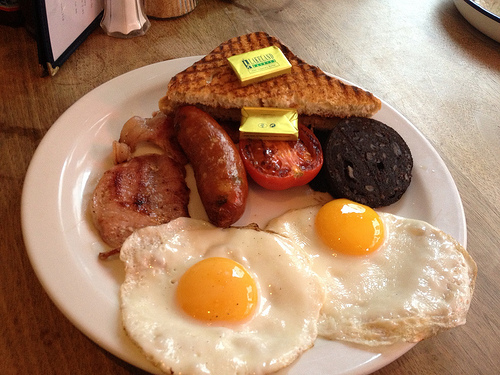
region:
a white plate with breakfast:
[21, 32, 476, 373]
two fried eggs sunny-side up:
[115, 199, 472, 374]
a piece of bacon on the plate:
[92, 116, 189, 245]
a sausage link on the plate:
[175, 112, 245, 225]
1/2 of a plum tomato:
[237, 126, 324, 193]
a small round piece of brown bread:
[322, 117, 414, 207]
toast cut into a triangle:
[155, 30, 380, 120]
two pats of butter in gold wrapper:
[223, 44, 298, 135]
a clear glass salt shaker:
[100, 3, 151, 35]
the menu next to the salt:
[29, 1, 101, 78]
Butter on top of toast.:
[230, 46, 290, 75]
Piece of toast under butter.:
[196, 55, 297, 95]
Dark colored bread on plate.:
[345, 132, 407, 169]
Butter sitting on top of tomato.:
[236, 108, 317, 147]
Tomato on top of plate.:
[248, 137, 314, 209]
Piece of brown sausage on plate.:
[196, 108, 246, 206]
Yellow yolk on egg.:
[326, 203, 378, 240]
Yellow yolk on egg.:
[202, 259, 255, 313]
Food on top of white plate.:
[77, 80, 373, 305]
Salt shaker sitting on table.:
[100, 4, 165, 40]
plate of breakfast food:
[16, 25, 476, 373]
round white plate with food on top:
[20, 45, 474, 374]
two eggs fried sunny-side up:
[118, 200, 477, 373]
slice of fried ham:
[86, 113, 189, 263]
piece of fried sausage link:
[171, 106, 248, 226]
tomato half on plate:
[241, 129, 325, 194]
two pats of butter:
[228, 43, 307, 141]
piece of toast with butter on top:
[164, 27, 384, 117]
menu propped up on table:
[21, 0, 98, 80]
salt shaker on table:
[96, 0, 154, 40]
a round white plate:
[19, 53, 470, 373]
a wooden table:
[6, 5, 498, 370]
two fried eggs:
[132, 200, 469, 374]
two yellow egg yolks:
[181, 200, 381, 319]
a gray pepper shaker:
[144, 0, 199, 19]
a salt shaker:
[100, 0, 143, 36]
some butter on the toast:
[227, 43, 289, 83]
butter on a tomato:
[237, 106, 300, 138]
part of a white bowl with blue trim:
[455, 0, 499, 39]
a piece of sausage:
[172, 107, 245, 226]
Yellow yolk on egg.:
[197, 272, 265, 322]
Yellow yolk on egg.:
[321, 200, 375, 256]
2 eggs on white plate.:
[142, 227, 411, 333]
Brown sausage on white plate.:
[188, 100, 239, 208]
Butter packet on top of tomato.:
[244, 105, 309, 145]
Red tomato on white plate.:
[255, 138, 292, 175]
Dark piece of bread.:
[343, 134, 392, 181]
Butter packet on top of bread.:
[242, 48, 289, 84]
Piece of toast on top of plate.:
[205, 50, 312, 115]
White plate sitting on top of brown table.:
[68, 84, 448, 335]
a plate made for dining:
[26, 59, 463, 373]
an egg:
[108, 215, 315, 370]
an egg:
[277, 195, 497, 347]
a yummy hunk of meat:
[160, 91, 250, 223]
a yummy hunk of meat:
[81, 120, 191, 237]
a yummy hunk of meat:
[316, 104, 419, 208]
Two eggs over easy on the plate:
[92, 202, 484, 356]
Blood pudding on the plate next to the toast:
[314, 99, 434, 218]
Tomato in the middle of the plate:
[208, 80, 318, 212]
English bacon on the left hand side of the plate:
[59, 131, 194, 281]